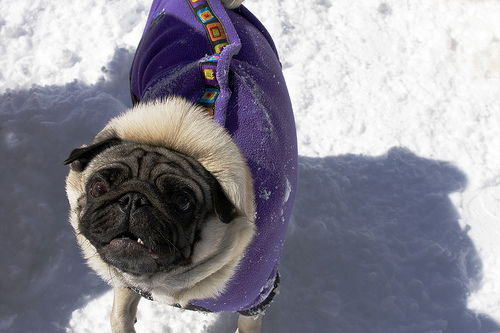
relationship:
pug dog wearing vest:
[62, 0, 298, 333] [129, 0, 300, 317]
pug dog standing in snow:
[62, 0, 298, 333] [0, 0, 500, 331]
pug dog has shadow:
[62, 0, 298, 333] [200, 144, 499, 331]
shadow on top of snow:
[200, 144, 499, 331] [0, 0, 500, 331]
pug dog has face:
[62, 0, 298, 333] [79, 162, 205, 276]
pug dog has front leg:
[62, 0, 298, 333] [235, 308, 268, 332]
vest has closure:
[129, 0, 300, 317] [206, 0, 242, 127]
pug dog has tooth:
[62, 0, 298, 333] [136, 236, 141, 243]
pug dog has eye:
[62, 0, 298, 333] [172, 193, 191, 211]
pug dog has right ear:
[62, 0, 298, 333] [62, 136, 123, 173]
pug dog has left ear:
[62, 0, 298, 333] [208, 173, 238, 224]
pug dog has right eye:
[62, 0, 298, 333] [90, 180, 109, 197]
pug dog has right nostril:
[62, 0, 298, 333] [118, 192, 133, 212]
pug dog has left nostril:
[62, 0, 298, 333] [130, 192, 151, 215]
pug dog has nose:
[62, 0, 298, 333] [117, 190, 150, 214]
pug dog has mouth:
[62, 0, 298, 333] [100, 228, 159, 259]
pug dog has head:
[62, 0, 298, 333] [63, 136, 241, 275]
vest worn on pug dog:
[129, 0, 300, 317] [62, 0, 298, 333]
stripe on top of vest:
[187, 0, 230, 122] [129, 0, 300, 317]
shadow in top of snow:
[200, 144, 499, 331] [0, 0, 500, 331]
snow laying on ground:
[0, 0, 500, 331] [1, 0, 499, 332]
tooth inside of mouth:
[140, 239, 145, 245] [100, 228, 159, 259]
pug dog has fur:
[62, 0, 298, 333] [64, 95, 256, 310]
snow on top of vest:
[281, 175, 292, 206] [129, 0, 300, 317]